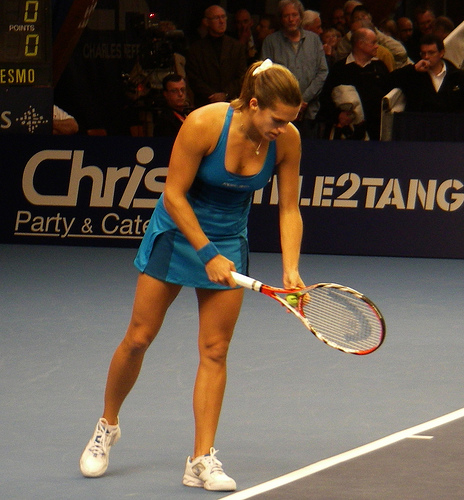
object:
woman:
[78, 58, 311, 492]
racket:
[229, 271, 384, 355]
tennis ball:
[285, 286, 307, 309]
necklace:
[239, 106, 264, 157]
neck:
[242, 104, 263, 138]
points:
[23, 33, 39, 56]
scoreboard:
[0, 0, 56, 88]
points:
[23, 0, 39, 22]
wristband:
[196, 240, 219, 263]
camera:
[140, 13, 187, 69]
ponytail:
[227, 55, 270, 113]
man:
[153, 73, 191, 138]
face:
[165, 79, 187, 110]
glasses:
[166, 87, 187, 93]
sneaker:
[181, 447, 239, 491]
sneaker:
[78, 416, 125, 477]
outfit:
[134, 103, 277, 290]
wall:
[0, 132, 463, 261]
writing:
[14, 211, 150, 240]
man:
[259, 0, 329, 141]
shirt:
[260, 30, 328, 120]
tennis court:
[0, 244, 464, 499]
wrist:
[196, 240, 218, 266]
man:
[378, 36, 464, 112]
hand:
[413, 58, 430, 71]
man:
[185, 5, 247, 109]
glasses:
[204, 13, 229, 21]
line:
[217, 407, 464, 499]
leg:
[102, 272, 183, 425]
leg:
[192, 286, 243, 458]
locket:
[255, 150, 261, 156]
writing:
[21, 145, 169, 209]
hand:
[205, 255, 236, 288]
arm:
[162, 112, 221, 267]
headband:
[251, 57, 274, 77]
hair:
[228, 59, 304, 114]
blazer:
[185, 34, 247, 104]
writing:
[252, 173, 463, 212]